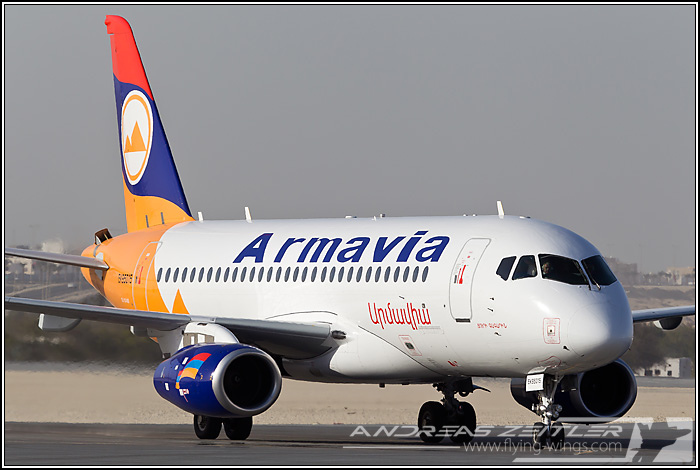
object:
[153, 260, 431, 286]
windows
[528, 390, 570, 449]
landing gear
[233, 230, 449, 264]
letter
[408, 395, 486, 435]
gear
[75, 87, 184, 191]
logo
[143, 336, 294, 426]
engine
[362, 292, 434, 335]
writing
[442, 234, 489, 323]
door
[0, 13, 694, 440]
airplane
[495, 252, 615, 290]
windshield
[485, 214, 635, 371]
cockpit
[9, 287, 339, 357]
wing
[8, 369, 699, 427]
dirt field